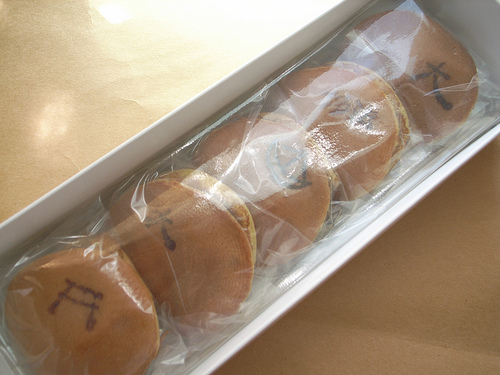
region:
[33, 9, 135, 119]
table in background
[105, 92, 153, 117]
textured lines on table surface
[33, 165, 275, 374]
food in plastic wrap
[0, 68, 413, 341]
food enclosed in wrapping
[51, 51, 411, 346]
brown food in packaging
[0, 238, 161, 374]
small round piece of food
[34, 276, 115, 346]
black lettering on food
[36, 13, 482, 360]
food with asian lettering on it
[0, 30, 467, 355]
food in a white box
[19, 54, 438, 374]
long white box containing food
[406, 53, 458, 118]
Foreign lettering on the food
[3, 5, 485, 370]
The food is in plastic wrapping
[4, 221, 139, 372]
A piece of food in the box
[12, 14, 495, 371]
The white box is on a table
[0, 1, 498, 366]
A white box holds the food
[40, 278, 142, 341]
A symbol is on the food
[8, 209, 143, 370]
The food is a gold and brown color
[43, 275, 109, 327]
The lettering on the food is black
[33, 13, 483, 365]
The plastic wrapping is clear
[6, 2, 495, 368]
The white box is open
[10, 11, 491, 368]
five folded pancakes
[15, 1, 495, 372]
folded pancakes are on a tray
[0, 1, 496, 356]
a rectangular tray on a table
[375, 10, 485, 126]
folded pancake has a chinese letter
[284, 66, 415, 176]
folded pancake has a chinese letter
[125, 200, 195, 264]
chinese letter on folded pancake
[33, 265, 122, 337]
chinese letter on folded pancake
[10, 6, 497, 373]
tray is over a brown surface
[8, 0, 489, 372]
folded pancake are in a white bag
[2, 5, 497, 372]
folded pancake are in a transparent bag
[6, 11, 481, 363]
Individually wrapped pancake sandwiches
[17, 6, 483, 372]
the cakes are six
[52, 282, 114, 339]
sign is on the cake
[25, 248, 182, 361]
cake is wrapped in plastic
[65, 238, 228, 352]
plastic is clear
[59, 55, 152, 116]
the paper is brown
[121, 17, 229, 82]
light reflection is on the surface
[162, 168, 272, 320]
the cake is circular in shape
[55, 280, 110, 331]
the letters are choclate in color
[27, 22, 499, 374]
the cakes are in cardboard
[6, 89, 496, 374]
the scene is indoors